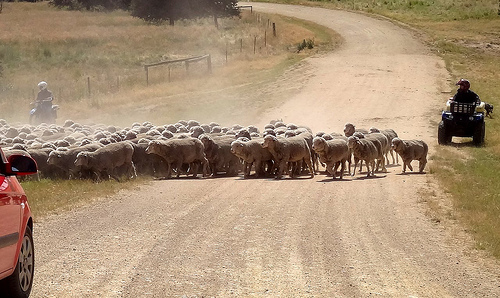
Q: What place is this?
A: It is a field.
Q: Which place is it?
A: It is a field.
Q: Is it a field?
A: Yes, it is a field.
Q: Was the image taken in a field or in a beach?
A: It was taken at a field.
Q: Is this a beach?
A: No, it is a field.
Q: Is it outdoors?
A: Yes, it is outdoors.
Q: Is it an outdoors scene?
A: Yes, it is outdoors.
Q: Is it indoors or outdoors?
A: It is outdoors.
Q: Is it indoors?
A: No, it is outdoors.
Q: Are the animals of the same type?
A: Yes, all the animals are sheep.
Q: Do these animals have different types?
A: No, all the animals are sheep.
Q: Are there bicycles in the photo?
A: No, there are no bicycles.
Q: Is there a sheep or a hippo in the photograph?
A: Yes, there is a sheep.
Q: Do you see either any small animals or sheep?
A: Yes, there is a small sheep.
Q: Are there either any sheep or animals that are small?
A: Yes, the sheep is small.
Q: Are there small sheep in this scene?
A: Yes, there is a small sheep.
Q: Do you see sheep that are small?
A: Yes, there is a sheep that is small.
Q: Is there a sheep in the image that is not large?
A: Yes, there is a small sheep.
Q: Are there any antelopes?
A: No, there are no antelopes.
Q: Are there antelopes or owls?
A: No, there are no antelopes or owls.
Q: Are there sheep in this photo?
A: Yes, there is a sheep.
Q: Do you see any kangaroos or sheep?
A: Yes, there is a sheep.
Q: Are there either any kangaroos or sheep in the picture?
A: Yes, there is a sheep.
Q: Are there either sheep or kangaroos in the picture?
A: Yes, there is a sheep.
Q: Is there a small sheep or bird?
A: Yes, there is a small sheep.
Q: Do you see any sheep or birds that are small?
A: Yes, the sheep is small.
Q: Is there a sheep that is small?
A: Yes, there is a small sheep.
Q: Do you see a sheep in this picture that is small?
A: Yes, there is a sheep that is small.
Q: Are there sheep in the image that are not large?
A: Yes, there is a small sheep.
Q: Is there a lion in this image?
A: No, there are no lions.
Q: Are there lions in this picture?
A: No, there are no lions.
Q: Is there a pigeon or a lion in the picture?
A: No, there are no lions or pigeons.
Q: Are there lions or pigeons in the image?
A: No, there are no lions or pigeons.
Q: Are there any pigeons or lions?
A: No, there are no lions or pigeons.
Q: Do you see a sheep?
A: Yes, there is a sheep.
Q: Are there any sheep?
A: Yes, there is a sheep.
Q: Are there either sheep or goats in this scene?
A: Yes, there is a sheep.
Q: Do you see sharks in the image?
A: No, there are no sharks.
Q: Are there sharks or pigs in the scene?
A: No, there are no sharks or pigs.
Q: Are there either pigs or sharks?
A: No, there are no sharks or pigs.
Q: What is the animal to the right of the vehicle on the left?
A: The animal is a sheep.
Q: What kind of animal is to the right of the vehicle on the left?
A: The animal is a sheep.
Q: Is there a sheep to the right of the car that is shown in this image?
A: Yes, there is a sheep to the right of the car.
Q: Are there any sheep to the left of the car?
A: No, the sheep is to the right of the car.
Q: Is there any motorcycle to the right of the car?
A: No, there is a sheep to the right of the car.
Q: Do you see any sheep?
A: Yes, there is a sheep.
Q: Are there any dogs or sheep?
A: Yes, there is a sheep.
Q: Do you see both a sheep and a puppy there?
A: No, there is a sheep but no puppys.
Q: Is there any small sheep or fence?
A: Yes, there is a small sheep.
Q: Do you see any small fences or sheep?
A: Yes, there is a small sheep.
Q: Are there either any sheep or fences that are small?
A: Yes, the sheep is small.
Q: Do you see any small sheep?
A: Yes, there is a small sheep.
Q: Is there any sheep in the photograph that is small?
A: Yes, there is a sheep that is small.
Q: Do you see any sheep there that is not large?
A: Yes, there is a small sheep.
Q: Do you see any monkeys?
A: No, there are no monkeys.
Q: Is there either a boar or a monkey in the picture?
A: No, there are no monkeys or boars.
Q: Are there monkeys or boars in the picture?
A: No, there are no monkeys or boars.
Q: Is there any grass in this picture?
A: Yes, there is grass.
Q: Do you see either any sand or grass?
A: Yes, there is grass.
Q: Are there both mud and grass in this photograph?
A: No, there is grass but no mud.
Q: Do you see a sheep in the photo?
A: Yes, there is a sheep.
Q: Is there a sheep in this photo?
A: Yes, there is a sheep.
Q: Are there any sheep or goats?
A: Yes, there is a sheep.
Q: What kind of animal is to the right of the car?
A: The animal is a sheep.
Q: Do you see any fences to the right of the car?
A: No, there is a sheep to the right of the car.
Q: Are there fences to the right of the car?
A: No, there is a sheep to the right of the car.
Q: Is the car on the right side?
A: No, the car is on the left of the image.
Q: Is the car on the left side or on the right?
A: The car is on the left of the image.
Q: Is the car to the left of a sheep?
A: Yes, the car is to the left of a sheep.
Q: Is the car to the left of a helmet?
A: No, the car is to the left of a sheep.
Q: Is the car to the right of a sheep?
A: No, the car is to the left of a sheep.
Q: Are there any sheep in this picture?
A: Yes, there is a sheep.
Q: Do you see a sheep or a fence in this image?
A: Yes, there is a sheep.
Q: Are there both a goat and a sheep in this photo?
A: No, there is a sheep but no goats.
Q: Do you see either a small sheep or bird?
A: Yes, there is a small sheep.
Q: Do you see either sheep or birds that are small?
A: Yes, the sheep is small.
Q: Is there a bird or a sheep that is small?
A: Yes, the sheep is small.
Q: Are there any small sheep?
A: Yes, there is a small sheep.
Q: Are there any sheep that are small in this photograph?
A: Yes, there is a small sheep.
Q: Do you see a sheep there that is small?
A: Yes, there is a sheep that is small.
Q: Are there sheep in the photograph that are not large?
A: Yes, there is a small sheep.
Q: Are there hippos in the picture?
A: No, there are no hippos.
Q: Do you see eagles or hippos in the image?
A: No, there are no hippos or eagles.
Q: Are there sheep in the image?
A: Yes, there is a sheep.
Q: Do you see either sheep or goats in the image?
A: Yes, there is a sheep.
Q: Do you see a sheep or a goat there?
A: Yes, there is a sheep.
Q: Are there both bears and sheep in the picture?
A: No, there is a sheep but no bears.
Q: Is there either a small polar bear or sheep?
A: Yes, there is a small sheep.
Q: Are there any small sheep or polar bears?
A: Yes, there is a small sheep.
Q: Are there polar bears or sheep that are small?
A: Yes, the sheep is small.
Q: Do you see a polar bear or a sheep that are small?
A: Yes, the sheep is small.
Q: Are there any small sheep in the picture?
A: Yes, there is a small sheep.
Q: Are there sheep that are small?
A: Yes, there is a sheep that is small.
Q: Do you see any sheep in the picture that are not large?
A: Yes, there is a small sheep.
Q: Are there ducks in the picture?
A: No, there are no ducks.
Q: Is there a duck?
A: No, there are no ducks.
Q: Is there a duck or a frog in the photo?
A: No, there are no ducks or frogs.